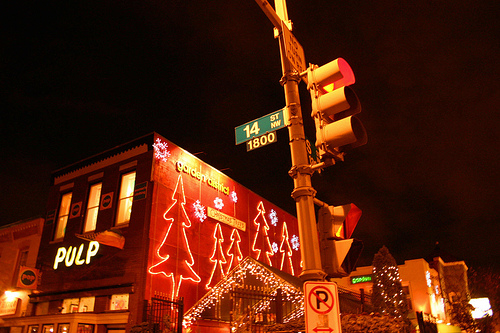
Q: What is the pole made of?
A: Metal.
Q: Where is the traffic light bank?
A: On the pole.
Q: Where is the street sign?
A: Behind the traffic lights.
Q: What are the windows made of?
A: Glass.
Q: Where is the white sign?
A: Low on the pole.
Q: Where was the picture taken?
A: A street corner.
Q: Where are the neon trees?
A: On the side of the building.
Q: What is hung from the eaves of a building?
A: Christmas lights.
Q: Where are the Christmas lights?
A: On the eaves of a building and a tree.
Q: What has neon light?
A: Pines trees.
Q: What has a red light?
A: The traffic light.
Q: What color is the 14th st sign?
A: Green.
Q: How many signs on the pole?
A: Two.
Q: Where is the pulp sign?
A: The building.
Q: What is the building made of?
A: Brick.